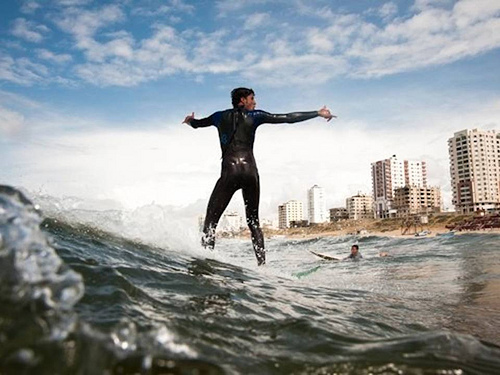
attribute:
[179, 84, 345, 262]
man — surfing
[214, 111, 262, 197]
wet suit — black, shiny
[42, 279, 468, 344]
water — dark, grey, white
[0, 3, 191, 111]
sky — blue, white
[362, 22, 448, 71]
clouds — white, puffy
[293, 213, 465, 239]
beach — brown, tan, sandy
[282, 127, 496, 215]
hotels — tall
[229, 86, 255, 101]
hair — dark, brown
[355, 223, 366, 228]
soil — brown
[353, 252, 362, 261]
shirt — grey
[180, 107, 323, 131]
arms — outstretched